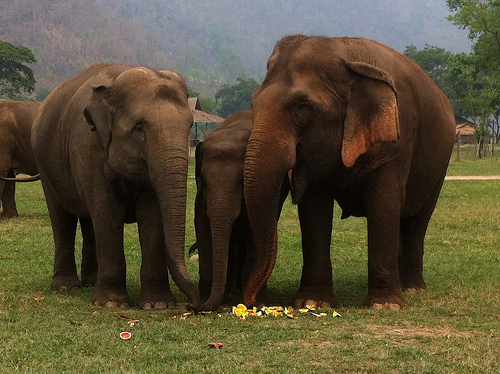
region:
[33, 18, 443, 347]
trio of elephants snacking on oranges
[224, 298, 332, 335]
oranges on the ground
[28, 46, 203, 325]
elephant with small ears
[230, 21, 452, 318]
elephant with two toned ears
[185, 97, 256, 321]
baby elephant by its mother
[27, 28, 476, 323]
family of elephants together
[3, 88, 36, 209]
partial elephant behind others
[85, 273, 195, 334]
elephant feet with large toenails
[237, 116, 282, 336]
orange tinted elephant trunk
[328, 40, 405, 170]
waving elephant ear with lighter edge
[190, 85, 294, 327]
a small elephant between two bigger elephants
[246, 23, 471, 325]
a large elephant standing on the right side of the smaller elephant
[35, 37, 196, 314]
a large elephant standing directly to the left of a small elephant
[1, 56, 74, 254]
an elephant in the back round who is only half visible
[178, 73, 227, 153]
a small hut behind the small elephant in the middle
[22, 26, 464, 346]
three elephants clearly visible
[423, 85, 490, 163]
a small hut behind the large elephant on the right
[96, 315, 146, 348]
a red circular object in front of the large elephant on the left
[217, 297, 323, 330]
yellow debris in front of the small elephant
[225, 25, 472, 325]
the largest elephant of the bunch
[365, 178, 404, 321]
the leg of an elephant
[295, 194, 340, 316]
the leg of an elephant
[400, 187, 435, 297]
the leg of an elephant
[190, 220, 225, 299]
the leg of an elephant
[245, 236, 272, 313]
the leg of an elephant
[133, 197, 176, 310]
the leg of an elephant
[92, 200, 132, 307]
the leg of an elephant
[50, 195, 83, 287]
the leg of an elephant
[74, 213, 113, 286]
the leg of an elephant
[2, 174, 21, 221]
the leg of an elephant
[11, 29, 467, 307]
A group of elephants.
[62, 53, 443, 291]
An elephant family.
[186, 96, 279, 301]
A baby elephant.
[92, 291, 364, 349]
Food on the ground for the elephants to eat.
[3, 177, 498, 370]
A large grassy area.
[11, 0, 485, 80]
A large area with many trees.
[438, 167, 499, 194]
A street way or pathway for travel.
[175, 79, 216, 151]
A shelter for people.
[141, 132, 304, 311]
The trunks of elephants.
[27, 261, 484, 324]
The feet of elephants.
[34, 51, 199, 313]
one of three elephants facing forward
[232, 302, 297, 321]
fruit snacks on ground for elephants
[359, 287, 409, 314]
a front foot on far right elephant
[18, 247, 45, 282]
grass where elephants are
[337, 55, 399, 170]
ear of elephant on far right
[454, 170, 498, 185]
sidewalk in back of elephants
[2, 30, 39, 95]
part of palm fronds behind elephants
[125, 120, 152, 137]
eye of elephant on the left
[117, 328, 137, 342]
pink fruit that's part of elephant's snack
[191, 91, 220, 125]
roof of an enclosure behind the elephants